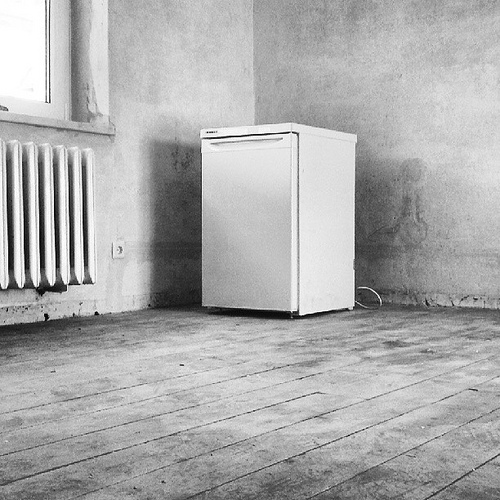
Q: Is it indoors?
A: Yes, it is indoors.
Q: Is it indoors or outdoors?
A: It is indoors.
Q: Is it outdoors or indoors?
A: It is indoors.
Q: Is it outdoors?
A: No, it is indoors.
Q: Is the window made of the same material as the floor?
A: No, the window is made of glass and the floor is made of wood.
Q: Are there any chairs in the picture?
A: No, there are no chairs.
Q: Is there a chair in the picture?
A: No, there are no chairs.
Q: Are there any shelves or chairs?
A: No, there are no chairs or shelves.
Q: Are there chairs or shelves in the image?
A: No, there are no chairs or shelves.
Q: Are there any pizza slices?
A: No, there are no pizza slices.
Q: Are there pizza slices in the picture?
A: No, there are no pizza slices.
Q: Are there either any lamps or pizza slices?
A: No, there are no pizza slices or lamps.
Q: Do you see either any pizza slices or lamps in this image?
A: No, there are no pizza slices or lamps.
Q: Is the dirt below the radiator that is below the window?
A: Yes, the dirt is below the radiator.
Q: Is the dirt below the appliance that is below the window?
A: Yes, the dirt is below the radiator.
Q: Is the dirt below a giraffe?
A: No, the dirt is below the radiator.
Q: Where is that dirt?
A: The dirt is on the floor.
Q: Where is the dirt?
A: The dirt is on the floor.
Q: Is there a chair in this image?
A: No, there are no chairs.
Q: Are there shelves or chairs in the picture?
A: No, there are no chairs or shelves.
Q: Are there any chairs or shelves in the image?
A: No, there are no chairs or shelves.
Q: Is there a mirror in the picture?
A: No, there are no mirrors.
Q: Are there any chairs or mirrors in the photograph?
A: No, there are no mirrors or chairs.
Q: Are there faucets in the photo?
A: No, there are no faucets.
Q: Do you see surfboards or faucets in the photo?
A: No, there are no faucets or surfboards.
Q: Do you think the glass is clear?
A: Yes, the glass is clear.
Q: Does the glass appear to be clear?
A: Yes, the glass is clear.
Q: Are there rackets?
A: No, there are no rackets.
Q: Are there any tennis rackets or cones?
A: No, there are no tennis rackets or cones.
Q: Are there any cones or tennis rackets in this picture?
A: No, there are no tennis rackets or cones.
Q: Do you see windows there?
A: Yes, there is a window.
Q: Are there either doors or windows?
A: Yes, there is a window.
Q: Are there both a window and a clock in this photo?
A: No, there is a window but no clocks.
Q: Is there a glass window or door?
A: Yes, there is a glass window.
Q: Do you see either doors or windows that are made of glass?
A: Yes, the window is made of glass.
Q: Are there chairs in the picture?
A: No, there are no chairs.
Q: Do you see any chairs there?
A: No, there are no chairs.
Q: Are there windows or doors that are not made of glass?
A: No, there is a window but it is made of glass.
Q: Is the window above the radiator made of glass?
A: Yes, the window is made of glass.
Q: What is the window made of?
A: The window is made of glass.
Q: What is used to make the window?
A: The window is made of glass.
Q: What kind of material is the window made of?
A: The window is made of glass.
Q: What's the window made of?
A: The window is made of glass.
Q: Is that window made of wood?
A: No, the window is made of glass.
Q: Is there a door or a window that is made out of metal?
A: No, there is a window but it is made of glass.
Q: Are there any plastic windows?
A: No, there is a window but it is made of glass.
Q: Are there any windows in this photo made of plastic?
A: No, there is a window but it is made of glass.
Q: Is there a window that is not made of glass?
A: No, there is a window but it is made of glass.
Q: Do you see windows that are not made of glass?
A: No, there is a window but it is made of glass.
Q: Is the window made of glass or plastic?
A: The window is made of glass.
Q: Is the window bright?
A: Yes, the window is bright.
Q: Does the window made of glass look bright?
A: Yes, the window is bright.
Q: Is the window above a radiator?
A: Yes, the window is above a radiator.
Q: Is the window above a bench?
A: No, the window is above a radiator.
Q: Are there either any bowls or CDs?
A: No, there are no bowls or cds.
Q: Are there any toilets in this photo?
A: No, there are no toilets.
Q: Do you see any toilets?
A: No, there are no toilets.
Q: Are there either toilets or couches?
A: No, there are no toilets or couches.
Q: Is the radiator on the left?
A: Yes, the radiator is on the left of the image.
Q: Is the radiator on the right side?
A: No, the radiator is on the left of the image.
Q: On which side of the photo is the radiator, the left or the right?
A: The radiator is on the left of the image.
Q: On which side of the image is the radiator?
A: The radiator is on the left of the image.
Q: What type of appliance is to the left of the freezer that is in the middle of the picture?
A: The appliance is a radiator.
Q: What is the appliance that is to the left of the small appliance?
A: The appliance is a radiator.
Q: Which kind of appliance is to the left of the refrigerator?
A: The appliance is a radiator.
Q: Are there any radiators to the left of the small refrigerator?
A: Yes, there is a radiator to the left of the freezer.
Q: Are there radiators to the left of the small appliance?
A: Yes, there is a radiator to the left of the freezer.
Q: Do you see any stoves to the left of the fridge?
A: No, there is a radiator to the left of the fridge.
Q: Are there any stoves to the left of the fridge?
A: No, there is a radiator to the left of the fridge.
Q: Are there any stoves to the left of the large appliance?
A: No, there is a radiator to the left of the fridge.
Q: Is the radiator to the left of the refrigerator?
A: Yes, the radiator is to the left of the refrigerator.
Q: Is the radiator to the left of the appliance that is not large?
A: Yes, the radiator is to the left of the refrigerator.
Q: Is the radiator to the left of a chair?
A: No, the radiator is to the left of the refrigerator.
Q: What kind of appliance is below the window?
A: The appliance is a radiator.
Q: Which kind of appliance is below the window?
A: The appliance is a radiator.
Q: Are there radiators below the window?
A: Yes, there is a radiator below the window.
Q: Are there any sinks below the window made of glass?
A: No, there is a radiator below the window.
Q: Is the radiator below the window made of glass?
A: Yes, the radiator is below the window.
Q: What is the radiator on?
A: The radiator is on the wall.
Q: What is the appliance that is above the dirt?
A: The appliance is a radiator.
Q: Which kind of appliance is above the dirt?
A: The appliance is a radiator.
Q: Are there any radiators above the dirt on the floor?
A: Yes, there is a radiator above the dirt.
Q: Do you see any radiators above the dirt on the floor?
A: Yes, there is a radiator above the dirt.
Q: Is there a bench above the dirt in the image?
A: No, there is a radiator above the dirt.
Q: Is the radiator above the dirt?
A: Yes, the radiator is above the dirt.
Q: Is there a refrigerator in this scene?
A: Yes, there is a refrigerator.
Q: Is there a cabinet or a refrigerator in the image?
A: Yes, there is a refrigerator.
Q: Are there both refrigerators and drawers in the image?
A: No, there is a refrigerator but no drawers.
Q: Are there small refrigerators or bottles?
A: Yes, there is a small refrigerator.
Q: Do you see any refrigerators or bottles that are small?
A: Yes, the refrigerator is small.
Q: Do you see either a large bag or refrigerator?
A: Yes, there is a large refrigerator.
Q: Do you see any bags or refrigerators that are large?
A: Yes, the refrigerator is large.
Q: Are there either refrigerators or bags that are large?
A: Yes, the refrigerator is large.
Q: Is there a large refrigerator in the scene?
A: Yes, there is a large refrigerator.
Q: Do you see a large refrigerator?
A: Yes, there is a large refrigerator.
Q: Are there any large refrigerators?
A: Yes, there is a large refrigerator.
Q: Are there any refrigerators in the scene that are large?
A: Yes, there is a refrigerator that is large.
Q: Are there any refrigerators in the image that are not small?
A: Yes, there is a large refrigerator.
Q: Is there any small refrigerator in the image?
A: Yes, there is a small refrigerator.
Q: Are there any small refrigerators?
A: Yes, there is a small refrigerator.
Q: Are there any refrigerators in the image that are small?
A: Yes, there is a refrigerator that is small.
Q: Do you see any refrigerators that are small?
A: Yes, there is a refrigerator that is small.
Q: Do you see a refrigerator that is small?
A: Yes, there is a refrigerator that is small.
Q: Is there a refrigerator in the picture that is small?
A: Yes, there is a refrigerator that is small.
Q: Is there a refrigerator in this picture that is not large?
A: Yes, there is a small refrigerator.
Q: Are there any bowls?
A: No, there are no bowls.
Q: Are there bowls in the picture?
A: No, there are no bowls.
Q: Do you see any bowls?
A: No, there are no bowls.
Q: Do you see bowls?
A: No, there are no bowls.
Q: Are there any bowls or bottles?
A: No, there are no bowls or bottles.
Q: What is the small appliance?
A: The appliance is a refrigerator.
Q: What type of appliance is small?
A: The appliance is a refrigerator.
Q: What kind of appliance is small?
A: The appliance is a refrigerator.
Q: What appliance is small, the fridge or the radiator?
A: The fridge is small.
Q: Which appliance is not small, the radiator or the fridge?
A: The radiator is not small.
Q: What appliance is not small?
A: The appliance is a radiator.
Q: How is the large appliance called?
A: The appliance is a refrigerator.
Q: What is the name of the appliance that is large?
A: The appliance is a refrigerator.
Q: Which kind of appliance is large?
A: The appliance is a refrigerator.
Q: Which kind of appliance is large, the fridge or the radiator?
A: The fridge is large.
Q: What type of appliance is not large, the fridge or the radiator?
A: The radiator is not large.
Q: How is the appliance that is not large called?
A: The appliance is a radiator.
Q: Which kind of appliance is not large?
A: The appliance is a radiator.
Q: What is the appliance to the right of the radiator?
A: The appliance is a refrigerator.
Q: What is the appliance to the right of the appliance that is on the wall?
A: The appliance is a refrigerator.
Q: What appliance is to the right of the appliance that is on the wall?
A: The appliance is a refrigerator.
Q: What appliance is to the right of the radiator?
A: The appliance is a refrigerator.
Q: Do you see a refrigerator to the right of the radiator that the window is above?
A: Yes, there is a refrigerator to the right of the radiator.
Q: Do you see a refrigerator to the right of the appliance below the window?
A: Yes, there is a refrigerator to the right of the radiator.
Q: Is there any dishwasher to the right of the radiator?
A: No, there is a refrigerator to the right of the radiator.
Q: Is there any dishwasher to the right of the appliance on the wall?
A: No, there is a refrigerator to the right of the radiator.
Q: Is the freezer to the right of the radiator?
A: Yes, the freezer is to the right of the radiator.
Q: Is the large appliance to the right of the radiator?
A: Yes, the freezer is to the right of the radiator.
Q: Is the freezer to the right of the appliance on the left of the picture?
A: Yes, the freezer is to the right of the radiator.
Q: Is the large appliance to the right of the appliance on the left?
A: Yes, the freezer is to the right of the radiator.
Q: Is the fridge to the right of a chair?
A: No, the fridge is to the right of the radiator.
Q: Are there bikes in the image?
A: No, there are no bikes.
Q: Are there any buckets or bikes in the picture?
A: No, there are no bikes or buckets.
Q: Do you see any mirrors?
A: No, there are no mirrors.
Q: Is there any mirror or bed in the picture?
A: No, there are no mirrors or beds.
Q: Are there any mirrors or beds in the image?
A: No, there are no mirrors or beds.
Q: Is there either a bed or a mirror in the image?
A: No, there are no mirrors or beds.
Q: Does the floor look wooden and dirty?
A: Yes, the floor is wooden and dirty.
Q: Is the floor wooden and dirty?
A: Yes, the floor is wooden and dirty.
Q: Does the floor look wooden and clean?
A: No, the floor is wooden but dirty.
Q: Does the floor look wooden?
A: Yes, the floor is wooden.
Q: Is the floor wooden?
A: Yes, the floor is wooden.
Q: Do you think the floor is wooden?
A: Yes, the floor is wooden.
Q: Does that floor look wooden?
A: Yes, the floor is wooden.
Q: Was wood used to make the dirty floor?
A: Yes, the floor is made of wood.